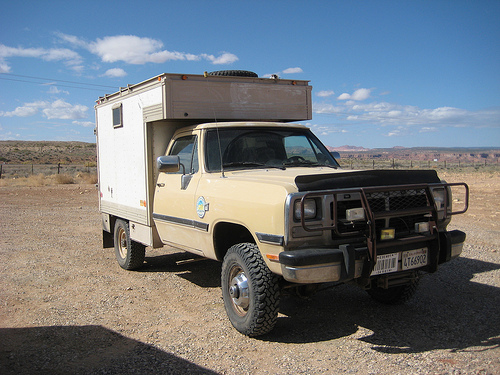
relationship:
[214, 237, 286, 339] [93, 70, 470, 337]
front tire of cab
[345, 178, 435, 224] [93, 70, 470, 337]
grill of cab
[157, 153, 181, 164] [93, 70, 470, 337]
mirror of cab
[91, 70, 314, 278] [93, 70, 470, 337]
cargo of cab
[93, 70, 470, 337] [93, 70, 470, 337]
cab with cab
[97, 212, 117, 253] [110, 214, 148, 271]
mud flap behind tire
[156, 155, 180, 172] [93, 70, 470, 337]
mirror on side of cab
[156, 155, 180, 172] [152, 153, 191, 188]
mirror on side of truck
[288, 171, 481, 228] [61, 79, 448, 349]
headlights on front of truck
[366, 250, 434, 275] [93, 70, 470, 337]
plates on front of cab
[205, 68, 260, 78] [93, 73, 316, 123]
tire on roof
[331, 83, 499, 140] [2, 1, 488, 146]
clouds in sky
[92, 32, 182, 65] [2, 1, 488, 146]
cloud in sky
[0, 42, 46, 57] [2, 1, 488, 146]
cloud in sky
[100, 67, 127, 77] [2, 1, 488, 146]
cloud in sky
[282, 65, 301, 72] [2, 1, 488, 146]
cloud in sky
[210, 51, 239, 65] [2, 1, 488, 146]
cloud in sky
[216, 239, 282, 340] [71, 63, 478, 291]
tire of truck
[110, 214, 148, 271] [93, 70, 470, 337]
tire of cab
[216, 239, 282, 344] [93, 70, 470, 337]
tire of cab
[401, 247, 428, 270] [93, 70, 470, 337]
license plate of cab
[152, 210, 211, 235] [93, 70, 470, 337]
black stripe on cab